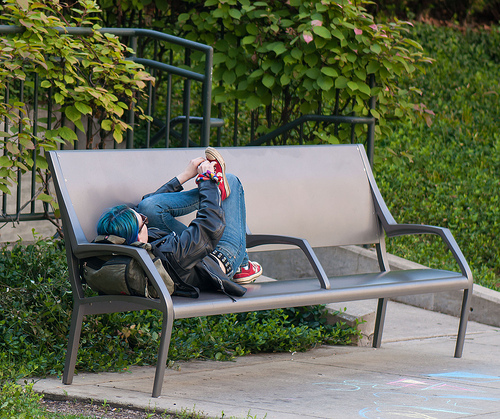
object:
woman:
[97, 148, 262, 298]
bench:
[46, 139, 473, 398]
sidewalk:
[36, 296, 499, 419]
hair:
[96, 204, 138, 244]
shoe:
[205, 147, 231, 200]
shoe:
[234, 260, 263, 284]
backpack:
[82, 257, 175, 297]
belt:
[211, 249, 233, 274]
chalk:
[429, 390, 497, 403]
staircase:
[0, 30, 374, 222]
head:
[96, 205, 148, 245]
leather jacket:
[149, 181, 225, 300]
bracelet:
[196, 170, 221, 184]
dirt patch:
[45, 389, 218, 419]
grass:
[0, 381, 46, 419]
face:
[131, 208, 149, 242]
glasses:
[137, 212, 148, 233]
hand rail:
[246, 114, 374, 146]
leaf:
[303, 30, 313, 43]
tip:
[303, 36, 312, 43]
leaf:
[361, 35, 370, 47]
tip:
[354, 29, 362, 34]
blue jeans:
[200, 171, 253, 266]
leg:
[63, 302, 85, 383]